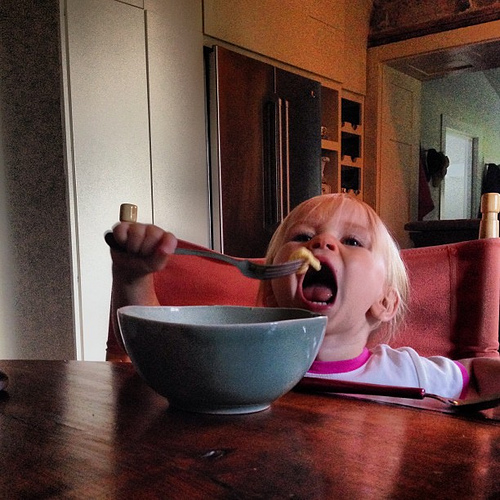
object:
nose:
[309, 230, 337, 253]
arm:
[409, 355, 499, 400]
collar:
[308, 346, 373, 374]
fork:
[105, 228, 306, 280]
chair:
[105, 193, 500, 364]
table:
[0, 359, 500, 500]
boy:
[104, 193, 500, 401]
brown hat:
[427, 148, 449, 187]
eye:
[340, 236, 364, 248]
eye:
[291, 233, 313, 242]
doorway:
[439, 127, 479, 219]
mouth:
[296, 255, 337, 310]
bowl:
[116, 303, 329, 416]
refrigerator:
[209, 45, 322, 257]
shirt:
[304, 344, 470, 402]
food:
[288, 246, 322, 275]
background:
[217, 63, 500, 239]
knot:
[201, 449, 226, 461]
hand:
[110, 221, 178, 275]